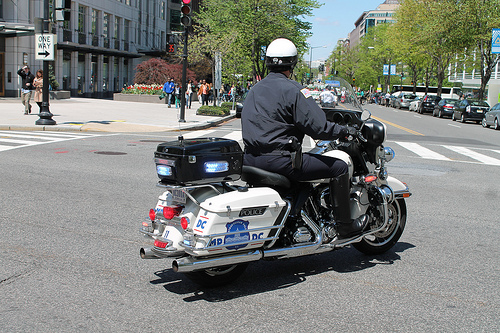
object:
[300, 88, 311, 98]
patch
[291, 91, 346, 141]
sleeve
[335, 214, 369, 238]
boot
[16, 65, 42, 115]
couple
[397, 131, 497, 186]
white paint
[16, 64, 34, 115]
pedestrian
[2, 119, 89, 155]
white paint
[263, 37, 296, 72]
helmet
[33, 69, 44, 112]
people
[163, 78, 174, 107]
people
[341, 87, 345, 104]
people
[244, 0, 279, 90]
trees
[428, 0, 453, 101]
trees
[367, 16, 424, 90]
trees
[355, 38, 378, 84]
trees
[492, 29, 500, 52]
banner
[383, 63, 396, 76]
banner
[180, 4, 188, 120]
pole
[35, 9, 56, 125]
pole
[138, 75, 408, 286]
motorcycle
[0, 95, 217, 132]
sidewalk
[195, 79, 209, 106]
person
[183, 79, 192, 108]
person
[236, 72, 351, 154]
black clothes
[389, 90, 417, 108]
cars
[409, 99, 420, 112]
cars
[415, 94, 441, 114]
cars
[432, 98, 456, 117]
cars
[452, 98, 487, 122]
cars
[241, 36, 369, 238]
cop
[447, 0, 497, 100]
trees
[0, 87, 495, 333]
road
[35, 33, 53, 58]
sign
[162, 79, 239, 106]
crowd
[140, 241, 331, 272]
exhaust pipes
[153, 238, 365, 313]
shadow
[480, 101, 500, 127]
car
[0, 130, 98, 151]
crosswalk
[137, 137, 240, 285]
back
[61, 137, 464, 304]
intersection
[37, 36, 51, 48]
one way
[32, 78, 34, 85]
arms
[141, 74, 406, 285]
bikw